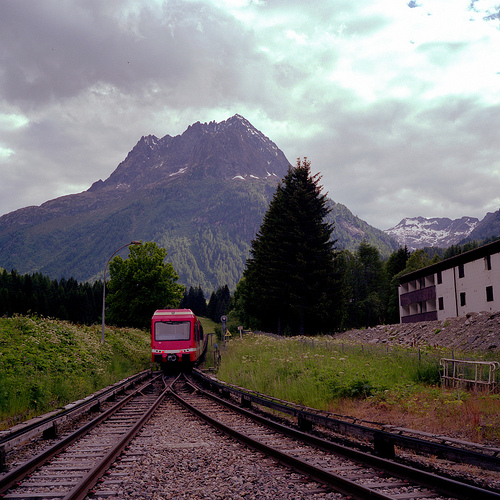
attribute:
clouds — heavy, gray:
[0, 1, 499, 230]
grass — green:
[0, 308, 152, 426]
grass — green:
[213, 325, 499, 409]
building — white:
[393, 239, 499, 320]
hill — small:
[335, 309, 499, 351]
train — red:
[149, 307, 203, 376]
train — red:
[151, 307, 202, 372]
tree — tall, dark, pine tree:
[234, 156, 347, 335]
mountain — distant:
[0, 113, 499, 303]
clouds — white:
[313, 137, 367, 193]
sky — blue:
[238, 24, 456, 131]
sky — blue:
[268, 11, 497, 114]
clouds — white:
[327, 71, 415, 171]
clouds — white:
[333, 74, 393, 135]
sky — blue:
[252, 0, 488, 193]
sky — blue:
[185, 41, 494, 207]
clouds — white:
[64, 33, 180, 103]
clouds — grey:
[88, 9, 168, 106]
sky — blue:
[12, 35, 494, 223]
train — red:
[140, 295, 226, 374]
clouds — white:
[407, 35, 450, 75]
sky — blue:
[313, 16, 493, 171]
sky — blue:
[313, 30, 496, 167]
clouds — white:
[336, 79, 431, 159]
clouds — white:
[426, 60, 487, 133]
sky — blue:
[336, 32, 491, 128]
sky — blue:
[253, 33, 326, 83]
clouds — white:
[194, 24, 390, 114]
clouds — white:
[58, 21, 159, 111]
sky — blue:
[69, 6, 474, 142]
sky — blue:
[284, 22, 404, 133]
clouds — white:
[91, 16, 267, 106]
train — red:
[137, 294, 224, 384]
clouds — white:
[365, 96, 411, 147]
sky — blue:
[286, 30, 466, 196]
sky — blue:
[290, 6, 494, 166]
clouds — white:
[368, 58, 441, 126]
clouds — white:
[388, 131, 497, 207]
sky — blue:
[319, 24, 490, 207]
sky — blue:
[254, 30, 455, 158]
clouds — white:
[279, 43, 340, 116]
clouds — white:
[110, 41, 246, 92]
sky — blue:
[102, 16, 436, 141]